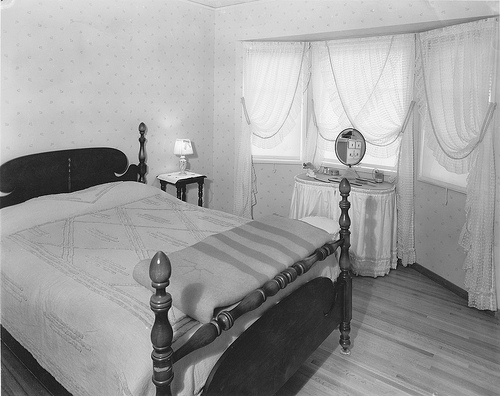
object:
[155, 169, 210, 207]
side table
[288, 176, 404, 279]
table skirt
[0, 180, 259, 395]
sheet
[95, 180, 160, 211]
pillow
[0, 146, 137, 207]
bed head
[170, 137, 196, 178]
lamp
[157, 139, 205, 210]
bedside table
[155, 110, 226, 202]
portrayal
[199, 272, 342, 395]
foot board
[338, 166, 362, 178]
fixture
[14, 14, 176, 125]
design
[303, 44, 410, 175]
window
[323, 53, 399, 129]
light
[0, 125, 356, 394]
bed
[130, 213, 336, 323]
blanket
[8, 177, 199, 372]
cover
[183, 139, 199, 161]
shade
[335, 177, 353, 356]
post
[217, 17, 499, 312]
curtains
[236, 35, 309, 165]
windows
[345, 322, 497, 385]
wood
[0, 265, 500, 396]
floors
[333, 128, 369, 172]
mirror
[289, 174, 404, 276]
table